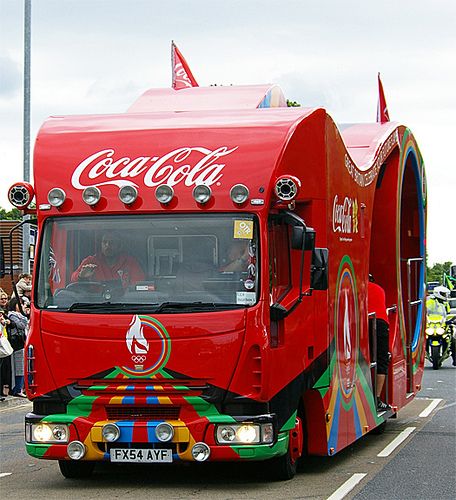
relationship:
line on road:
[332, 478, 362, 495] [433, 470, 441, 475]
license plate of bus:
[109, 438, 175, 464] [232, 118, 334, 171]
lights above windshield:
[138, 185, 250, 209] [35, 210, 252, 306]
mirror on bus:
[310, 245, 327, 297] [232, 118, 334, 171]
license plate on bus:
[109, 438, 175, 464] [232, 118, 334, 171]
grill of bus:
[113, 404, 168, 417] [232, 118, 334, 171]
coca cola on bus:
[69, 145, 238, 177] [232, 118, 334, 171]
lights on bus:
[138, 185, 250, 209] [232, 118, 334, 171]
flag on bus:
[168, 24, 206, 89] [8, 49, 428, 479]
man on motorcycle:
[415, 266, 451, 323] [428, 319, 453, 337]